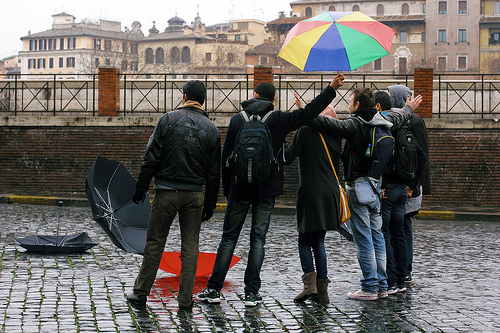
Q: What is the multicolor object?
A: Umbrella.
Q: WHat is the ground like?
A: Cobblestone.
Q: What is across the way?
A: Buildings.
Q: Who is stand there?
A: Group of men.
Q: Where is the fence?
A: Above wall.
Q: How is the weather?
A: Rainy.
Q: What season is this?
A: Autumn.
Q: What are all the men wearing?
A: Jackets.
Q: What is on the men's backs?
A: Backpacks.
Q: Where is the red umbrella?
A: Ground.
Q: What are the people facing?
A: Wall.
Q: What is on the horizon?
A: Buildings.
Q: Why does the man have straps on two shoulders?
A: To hold back pack.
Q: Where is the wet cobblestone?
A: Under the people.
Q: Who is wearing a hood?
A: Person of the right end.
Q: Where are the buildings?
A: Other side of fence.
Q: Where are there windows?
A: Buildings.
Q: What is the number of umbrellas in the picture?
A: Four.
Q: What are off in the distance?
A: Buildings.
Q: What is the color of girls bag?
A: Orange.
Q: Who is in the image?
A: People.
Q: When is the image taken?
A: In rain.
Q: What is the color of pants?
A: Black.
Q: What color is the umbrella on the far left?
A: Black.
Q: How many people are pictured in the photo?
A: Six.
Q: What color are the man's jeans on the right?
A: Blue.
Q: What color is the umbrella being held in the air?
A: Multi-colored.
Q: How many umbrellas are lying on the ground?
A: Two.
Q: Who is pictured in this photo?
A: A group of people.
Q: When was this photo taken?
A: Daytime.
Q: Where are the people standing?
A: Outdoors in the rain.